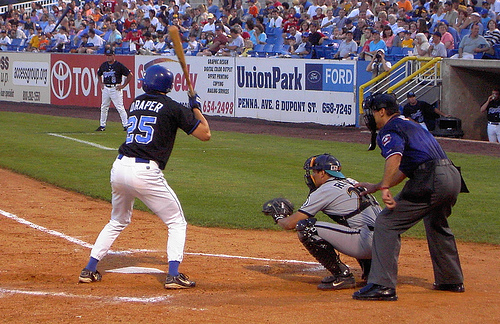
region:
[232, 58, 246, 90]
Blue letter on a white board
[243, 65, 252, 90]
Blue letter on a white board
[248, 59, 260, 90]
Blue letter on a white board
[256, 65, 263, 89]
Blue letter on a white board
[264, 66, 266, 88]
Blue letter on a white board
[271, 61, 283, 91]
Blue letter on a white board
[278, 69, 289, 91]
Blue letter on a white board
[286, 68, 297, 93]
Blue letter on a white board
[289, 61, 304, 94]
Blue letter on a white board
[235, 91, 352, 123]
Blue letter on a white board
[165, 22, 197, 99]
a wooden bat in a batter's hands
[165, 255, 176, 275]
blue socks on a batter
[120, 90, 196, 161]
a black shirt on a batter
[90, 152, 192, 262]
white pants on a batter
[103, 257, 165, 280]
a white home pate under a batter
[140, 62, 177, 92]
a blue helmet on a batter's head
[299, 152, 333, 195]
a catcher's mask on a catcher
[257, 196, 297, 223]
a black catcher's mitt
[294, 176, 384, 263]
a gray uniform on a catcher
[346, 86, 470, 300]
an umpire behind a catcher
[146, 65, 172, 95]
THE HELMET IS BLUE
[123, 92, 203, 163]
the shirt is black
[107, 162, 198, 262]
the pants are white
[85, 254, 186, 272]
the socks are blue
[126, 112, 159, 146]
25 is on the table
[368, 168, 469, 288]
the pants are grey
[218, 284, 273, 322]
the ground is brown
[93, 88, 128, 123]
the pants are white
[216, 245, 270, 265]
the line is white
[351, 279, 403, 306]
the shoes are black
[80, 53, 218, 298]
man wearing black shirt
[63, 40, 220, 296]
man wearing blue helmet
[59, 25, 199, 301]
man wearing white pants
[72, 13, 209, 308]
man holding baseball bat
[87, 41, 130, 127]
man standing on base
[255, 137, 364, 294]
man holding baseball mitt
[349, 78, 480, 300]
man wearing black face protector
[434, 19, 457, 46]
woman wearing pink shirt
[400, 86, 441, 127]
man wearing black baseball cap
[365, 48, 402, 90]
man taking pictures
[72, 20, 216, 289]
baseball player preparing to hit ball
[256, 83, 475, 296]
catcher and umpire preparing for pitch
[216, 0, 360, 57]
spectators in the stands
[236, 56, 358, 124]
Union Park Ford advertisement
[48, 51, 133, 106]
red Toyota banner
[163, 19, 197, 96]
wooden baseball bat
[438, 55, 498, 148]
corner portion of dugout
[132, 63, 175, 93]
blue batter's helmet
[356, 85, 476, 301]
umpire with hand on catcher's back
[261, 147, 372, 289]
catcher preparing to catch pitch